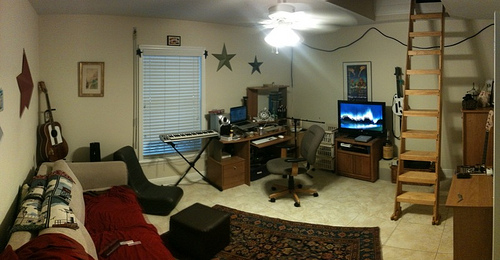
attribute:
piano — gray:
[156, 125, 224, 195]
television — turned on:
[343, 97, 404, 145]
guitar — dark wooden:
[31, 75, 72, 159]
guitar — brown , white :
[26, 69, 79, 178]